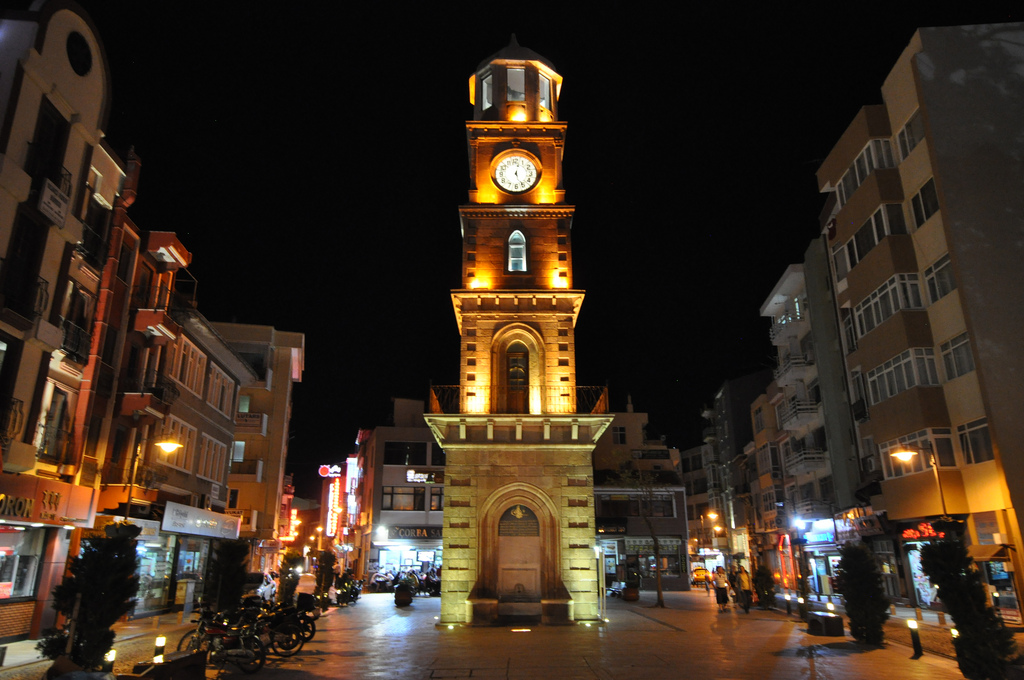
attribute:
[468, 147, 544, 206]
clock — round, illuminated, white, black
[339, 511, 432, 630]
lights — blue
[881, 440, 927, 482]
light — yellow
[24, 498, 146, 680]
tree — lime green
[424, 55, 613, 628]
tower — lit up